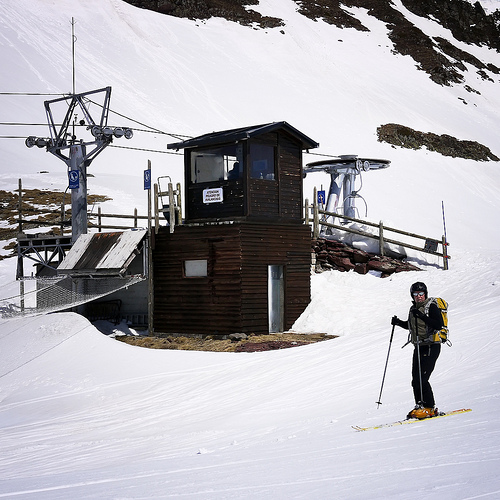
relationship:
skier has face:
[392, 282, 448, 421] [412, 291, 428, 303]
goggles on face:
[411, 290, 426, 298] [412, 291, 428, 303]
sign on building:
[203, 188, 225, 203] [150, 122, 311, 332]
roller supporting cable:
[92, 124, 103, 136] [4, 120, 193, 142]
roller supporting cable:
[102, 126, 114, 140] [4, 120, 193, 142]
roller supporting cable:
[114, 126, 123, 141] [4, 120, 193, 142]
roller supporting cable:
[124, 127, 134, 142] [4, 120, 193, 142]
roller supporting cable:
[24, 137, 35, 149] [0, 133, 186, 158]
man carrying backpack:
[392, 282, 448, 421] [429, 297, 450, 346]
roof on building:
[168, 121, 319, 152] [150, 122, 311, 332]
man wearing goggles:
[392, 282, 448, 421] [411, 290, 426, 298]